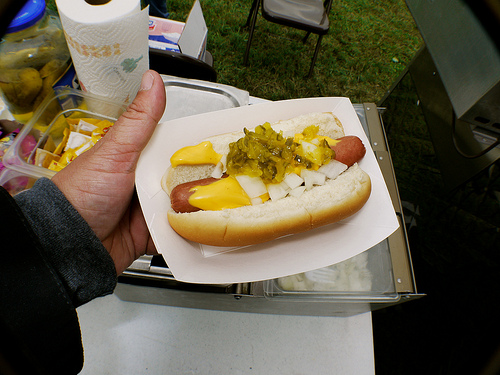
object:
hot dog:
[171, 136, 367, 213]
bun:
[159, 111, 371, 247]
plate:
[134, 97, 401, 285]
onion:
[235, 174, 269, 200]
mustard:
[211, 182, 233, 210]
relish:
[226, 122, 300, 181]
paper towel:
[55, 0, 149, 120]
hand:
[47, 70, 367, 280]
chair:
[243, 0, 332, 78]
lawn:
[348, 0, 426, 45]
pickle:
[2, 84, 72, 112]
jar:
[0, 0, 83, 142]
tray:
[157, 74, 250, 126]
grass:
[46, 0, 297, 107]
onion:
[284, 171, 304, 189]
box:
[147, 0, 209, 65]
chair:
[149, 46, 220, 82]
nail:
[140, 71, 156, 91]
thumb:
[76, 69, 167, 238]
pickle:
[2, 45, 67, 70]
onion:
[300, 169, 326, 186]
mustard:
[50, 160, 62, 169]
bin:
[1, 85, 133, 181]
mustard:
[64, 154, 70, 159]